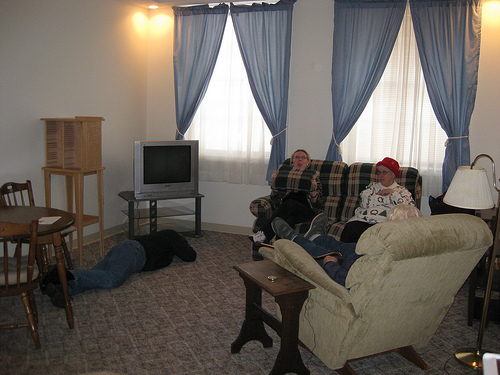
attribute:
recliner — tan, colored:
[265, 212, 493, 363]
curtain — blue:
[174, 0, 291, 183]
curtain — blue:
[325, 2, 481, 194]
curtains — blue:
[168, 1, 484, 183]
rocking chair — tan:
[244, 205, 464, 370]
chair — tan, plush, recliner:
[248, 0, 491, 173]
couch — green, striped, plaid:
[257, 145, 427, 270]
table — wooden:
[5, 172, 104, 325]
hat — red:
[374, 153, 398, 178]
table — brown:
[225, 257, 312, 374]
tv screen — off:
[126, 134, 203, 191]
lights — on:
[128, 10, 174, 36]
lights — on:
[477, 0, 498, 20]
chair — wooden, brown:
[0, 220, 45, 352]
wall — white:
[2, 4, 152, 249]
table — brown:
[4, 205, 86, 345]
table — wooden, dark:
[2, 202, 85, 330]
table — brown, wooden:
[89, 207, 360, 366]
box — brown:
[36, 115, 108, 175]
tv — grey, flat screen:
[132, 139, 199, 201]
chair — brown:
[274, 231, 472, 351]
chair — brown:
[6, 226, 42, 338]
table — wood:
[2, 193, 97, 324]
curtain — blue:
[166, 3, 286, 139]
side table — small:
[232, 258, 315, 373]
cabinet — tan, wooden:
[40, 112, 104, 267]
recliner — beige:
[263, 209, 485, 371]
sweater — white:
[344, 179, 413, 221]